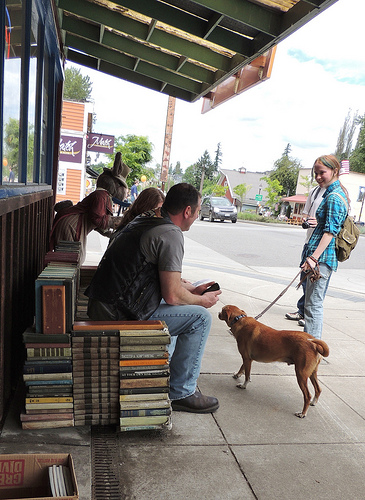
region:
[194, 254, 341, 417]
brown dog on a leash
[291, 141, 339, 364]
girl with blue plaid shirt and green backpack walking dog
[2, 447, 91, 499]
cardboard box of books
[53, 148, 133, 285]
rabbit mascot wearing clothes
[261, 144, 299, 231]
trees in the distance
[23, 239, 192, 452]
bench made of books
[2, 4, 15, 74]
open sign in the window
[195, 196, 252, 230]
gray car driving down the street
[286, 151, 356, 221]
white building across the street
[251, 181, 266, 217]
green street sign attached to street light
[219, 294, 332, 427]
beautiful brown adult dog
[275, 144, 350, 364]
young lady with long dark hair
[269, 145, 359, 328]
young lady with blue plaid shirt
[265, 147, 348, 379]
young girl wearing blue jeans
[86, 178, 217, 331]
man wearing black leather vest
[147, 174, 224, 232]
man with short brown hair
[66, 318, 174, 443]
stacks of different size books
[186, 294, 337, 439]
gray concrete sidewalk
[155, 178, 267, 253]
vehicle driving down the black top road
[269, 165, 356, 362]
young lady with large backpack on her back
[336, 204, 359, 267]
Backpack on the back of person.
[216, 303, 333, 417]
Dog on the street.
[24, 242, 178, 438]
Bench made of old books.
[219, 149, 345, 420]
Girl with dog on leash.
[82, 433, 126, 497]
Drain on the sidewalk.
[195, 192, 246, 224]
Car in the background.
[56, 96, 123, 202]
Advertising on the building.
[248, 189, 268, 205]
Green sign on the street.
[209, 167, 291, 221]
Barn shaped building in the background.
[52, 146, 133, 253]
Statue of animal behind men.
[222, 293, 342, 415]
dog on leash standing on sidewalk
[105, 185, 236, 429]
man wearing leather vest and blue jeans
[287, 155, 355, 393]
girl with green backpack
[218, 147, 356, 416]
smiling girl with dog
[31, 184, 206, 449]
bench made out of books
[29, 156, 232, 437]
man sitting on bench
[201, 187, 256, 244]
car driving down street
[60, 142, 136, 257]
mad hatter rabbit wearing hat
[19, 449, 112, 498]
cardboard box filled with books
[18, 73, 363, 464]
people talking in urban area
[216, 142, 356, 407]
young woman with dog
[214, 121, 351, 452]
dog with a young woman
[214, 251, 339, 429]
dog on a leash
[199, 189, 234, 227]
car at an intersection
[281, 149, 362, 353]
young woman with backpack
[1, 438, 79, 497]
box of books on sidewalk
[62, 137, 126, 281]
large rabbit leaning forward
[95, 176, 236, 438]
man wearing jeans